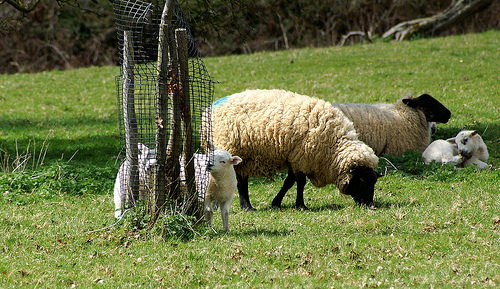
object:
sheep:
[199, 87, 397, 211]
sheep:
[420, 130, 489, 172]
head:
[400, 92, 453, 125]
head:
[205, 148, 243, 173]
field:
[0, 30, 499, 288]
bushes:
[0, 0, 499, 73]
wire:
[113, 0, 215, 235]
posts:
[120, 29, 137, 208]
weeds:
[0, 135, 51, 173]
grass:
[0, 29, 499, 289]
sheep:
[329, 93, 454, 164]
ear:
[230, 155, 245, 165]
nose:
[204, 165, 221, 170]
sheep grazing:
[347, 198, 384, 214]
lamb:
[112, 148, 243, 233]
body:
[201, 88, 340, 212]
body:
[330, 98, 431, 161]